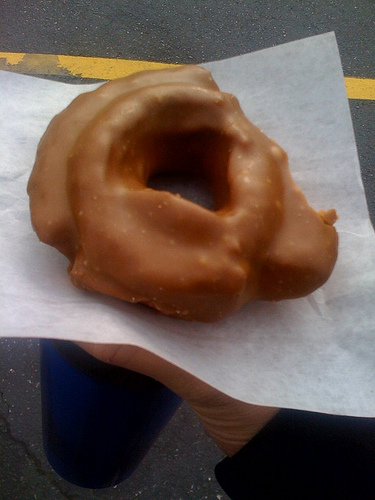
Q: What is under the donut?
A: Paper.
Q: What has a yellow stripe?
A: Street.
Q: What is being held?
A: Donut.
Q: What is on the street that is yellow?
A: Stripe.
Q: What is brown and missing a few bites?
A: Donut.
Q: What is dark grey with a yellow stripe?
A: Street.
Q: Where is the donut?
A: On tissue paper.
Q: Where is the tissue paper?
A: Under the donut.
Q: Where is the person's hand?
A: Under the tissue paper.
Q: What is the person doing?
A: Holding the donut.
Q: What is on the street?
A: A yellow painted line.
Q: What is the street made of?
A: Asphalt.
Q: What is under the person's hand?
A: A blue cup.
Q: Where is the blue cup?
A: Under the person's hand.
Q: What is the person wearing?
A: A black long sleeved top.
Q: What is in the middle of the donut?
A: Hole.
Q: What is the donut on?
A: White paper.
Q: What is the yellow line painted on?
A: Pavement.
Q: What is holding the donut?
A: Hand.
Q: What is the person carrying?
A: Donut and blue mug.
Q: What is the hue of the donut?
A: Brown.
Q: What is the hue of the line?
A: Yellow.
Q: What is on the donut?
A: Glaze.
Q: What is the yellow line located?
A: Road.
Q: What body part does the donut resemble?
A: Ear.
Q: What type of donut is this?
A: Glazed.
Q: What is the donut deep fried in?
A: Oil.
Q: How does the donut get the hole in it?
A: Cut out.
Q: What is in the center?
A: A donut.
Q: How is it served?
A: On a napkin.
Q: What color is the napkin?
A: White.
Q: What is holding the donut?
A: A hand.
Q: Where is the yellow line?
A: On the street.